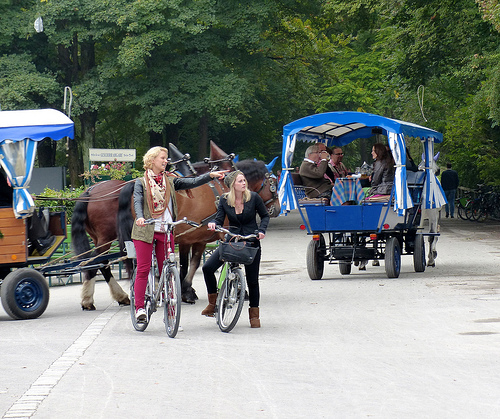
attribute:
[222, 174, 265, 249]
woman — blonde, pointing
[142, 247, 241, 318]
bikes — parked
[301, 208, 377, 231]
carriage — blue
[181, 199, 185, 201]
horse — brown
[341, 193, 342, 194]
tablecloth — pink, plaid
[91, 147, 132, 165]
sign — blue, white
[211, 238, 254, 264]
basket — black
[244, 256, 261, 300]
jeans — black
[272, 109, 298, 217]
curtains — blue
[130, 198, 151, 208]
jacket — gray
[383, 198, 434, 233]
wagon — blue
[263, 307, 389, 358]
road — paved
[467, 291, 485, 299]
mark — black, spotted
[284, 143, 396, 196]
people — sitting